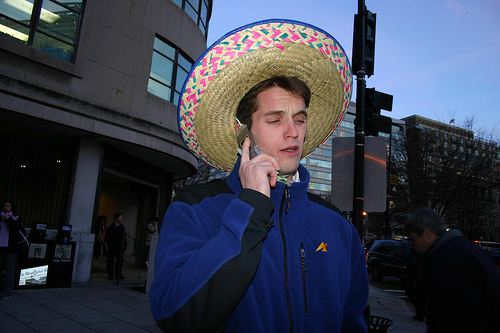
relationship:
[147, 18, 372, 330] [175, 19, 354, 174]
man wearing hat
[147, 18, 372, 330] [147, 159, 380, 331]
man wearing jacket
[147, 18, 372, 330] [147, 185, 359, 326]
man wearing jacket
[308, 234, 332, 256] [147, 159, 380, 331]
insignia on jacket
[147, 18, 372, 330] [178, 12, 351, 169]
man wearing hat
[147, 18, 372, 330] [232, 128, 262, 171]
man using cell phone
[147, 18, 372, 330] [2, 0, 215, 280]
man standing in front of building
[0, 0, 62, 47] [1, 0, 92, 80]
lights behind window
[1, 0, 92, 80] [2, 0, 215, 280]
window on building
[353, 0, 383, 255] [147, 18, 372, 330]
traffic light behind man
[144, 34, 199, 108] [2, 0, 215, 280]
window on building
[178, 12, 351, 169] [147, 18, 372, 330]
hat worn by man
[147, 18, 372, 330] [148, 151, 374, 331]
man wearing fleece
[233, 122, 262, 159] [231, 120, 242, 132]
cellphone next to ear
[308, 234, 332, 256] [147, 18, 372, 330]
insignia on man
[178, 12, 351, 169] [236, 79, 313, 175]
hat on man's head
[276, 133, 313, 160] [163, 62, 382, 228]
mouth on man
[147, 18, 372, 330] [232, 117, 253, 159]
man holding phone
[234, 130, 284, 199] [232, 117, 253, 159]
hand holding phone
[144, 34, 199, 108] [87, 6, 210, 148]
window on building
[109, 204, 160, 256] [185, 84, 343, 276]
jacket on man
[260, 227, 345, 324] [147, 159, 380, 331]
zipper pocket on jacket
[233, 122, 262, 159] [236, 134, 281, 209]
cellphone in hand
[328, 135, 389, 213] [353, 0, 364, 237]
sign hanging on post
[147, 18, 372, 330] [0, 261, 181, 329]
man walking on side walk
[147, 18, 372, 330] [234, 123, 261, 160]
man talking on cell phone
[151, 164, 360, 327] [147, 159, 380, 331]
stripes on jacket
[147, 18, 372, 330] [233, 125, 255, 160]
man on phone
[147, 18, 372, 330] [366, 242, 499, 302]
man next to street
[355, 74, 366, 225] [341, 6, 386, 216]
sign on pole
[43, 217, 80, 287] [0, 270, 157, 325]
newspaper box on sidewalk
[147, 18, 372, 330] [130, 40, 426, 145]
man wears sombrero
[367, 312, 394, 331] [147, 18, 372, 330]
bin behind man